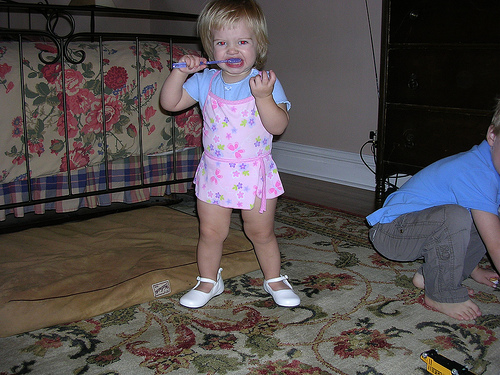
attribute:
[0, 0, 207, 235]
frame — metal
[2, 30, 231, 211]
frame — metal 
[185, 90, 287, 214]
dress — pink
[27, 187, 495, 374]
rug — area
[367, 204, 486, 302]
pants — gray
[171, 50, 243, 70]
toothbrush — purple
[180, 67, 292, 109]
shirt — blue, light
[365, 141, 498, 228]
shirt — blue , short sleeved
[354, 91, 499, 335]
boy — young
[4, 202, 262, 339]
pillow — brown, light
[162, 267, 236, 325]
shoe — white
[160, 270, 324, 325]
shoes — white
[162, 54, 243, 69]
toothbrush — blue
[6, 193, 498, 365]
area rug — flower patterned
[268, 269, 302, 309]
shoe — white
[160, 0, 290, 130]
toothbrush — purple  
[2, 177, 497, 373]
rug — area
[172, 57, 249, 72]
toothbrush — purple 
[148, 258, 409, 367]
shoes — white 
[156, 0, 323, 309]
girl — little 